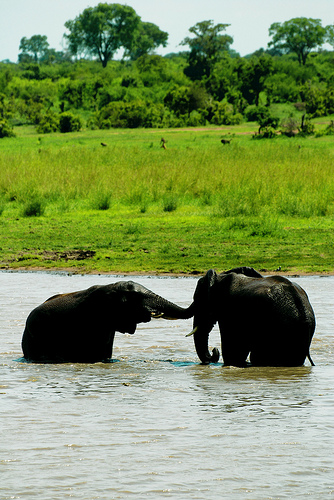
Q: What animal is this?
A: Elephant.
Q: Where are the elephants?
A: Water.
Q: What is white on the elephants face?
A: Tusks.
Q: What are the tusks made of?
A: Ivory.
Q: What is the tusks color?
A: White.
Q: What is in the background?
A: Trees.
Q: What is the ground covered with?
A: Grass.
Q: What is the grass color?
A: Green.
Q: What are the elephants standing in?
A: A river.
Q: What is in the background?
A: Trees and grass.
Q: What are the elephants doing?
A: Playing in the water.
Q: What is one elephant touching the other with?
A: Its trunk.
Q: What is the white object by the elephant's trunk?
A: Tusk.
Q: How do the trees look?
A: Green and leafy.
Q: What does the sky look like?
A: Blue and clear.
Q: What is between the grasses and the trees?
A: Some other animals.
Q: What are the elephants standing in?
A: Water.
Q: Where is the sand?
A: On the water's edge.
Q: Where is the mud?
A: On the water's edge.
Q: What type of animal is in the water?
A: Elephant.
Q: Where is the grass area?
A: At the water's edge.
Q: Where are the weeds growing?
A: In the grass.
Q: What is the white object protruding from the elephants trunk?
A: Tusk.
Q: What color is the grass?
A: Green.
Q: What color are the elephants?
A: Black.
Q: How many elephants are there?
A: Two.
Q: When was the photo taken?
A: Daytime.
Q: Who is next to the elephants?
A: No one.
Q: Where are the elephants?
A: In water.